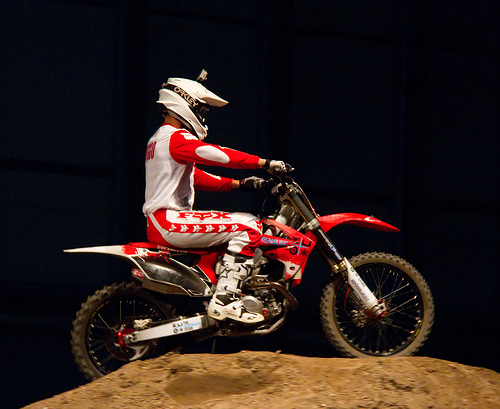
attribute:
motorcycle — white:
[54, 157, 438, 384]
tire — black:
[315, 245, 440, 367]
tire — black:
[68, 275, 190, 377]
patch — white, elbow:
[195, 142, 230, 167]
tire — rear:
[68, 278, 175, 373]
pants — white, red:
[143, 204, 265, 276]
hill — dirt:
[13, 347, 497, 407]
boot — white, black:
[207, 257, 265, 322]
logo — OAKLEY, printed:
[169, 85, 201, 110]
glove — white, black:
[243, 172, 263, 188]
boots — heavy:
[207, 256, 266, 321]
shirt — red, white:
[140, 128, 276, 215]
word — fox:
[180, 199, 228, 228]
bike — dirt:
[40, 195, 444, 385]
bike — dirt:
[64, 174, 438, 399]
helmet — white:
[154, 65, 234, 137]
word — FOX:
[173, 197, 229, 229]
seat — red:
[134, 233, 217, 283]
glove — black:
[267, 154, 285, 177]